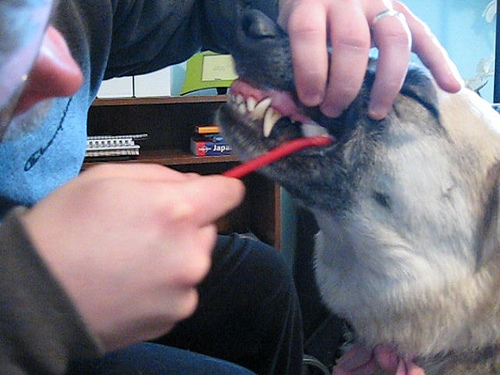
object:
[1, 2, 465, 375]
person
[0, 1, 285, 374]
sweatshirt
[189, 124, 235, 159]
stack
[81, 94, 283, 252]
bookcase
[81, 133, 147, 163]
binder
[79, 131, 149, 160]
tablet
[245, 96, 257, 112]
tooth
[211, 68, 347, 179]
mouth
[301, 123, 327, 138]
bristles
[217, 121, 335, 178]
toothbrush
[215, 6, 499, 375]
dog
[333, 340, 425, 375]
bow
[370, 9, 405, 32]
ring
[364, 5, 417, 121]
finger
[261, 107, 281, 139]
tooth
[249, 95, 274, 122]
tooth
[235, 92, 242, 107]
tooth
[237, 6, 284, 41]
nose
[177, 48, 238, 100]
green frame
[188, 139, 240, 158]
books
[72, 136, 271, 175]
shelf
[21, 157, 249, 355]
hand